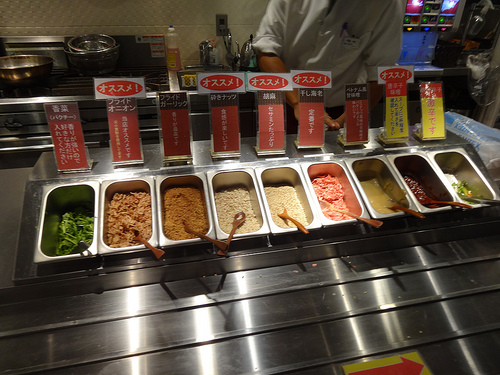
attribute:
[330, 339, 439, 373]
arrow — red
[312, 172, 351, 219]
food — pink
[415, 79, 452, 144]
sign — red , yellow 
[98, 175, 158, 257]
container — silver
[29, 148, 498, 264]
buffet — metal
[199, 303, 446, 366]
surface — reflective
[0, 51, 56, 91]
pan — reflective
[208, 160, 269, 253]
container — metal 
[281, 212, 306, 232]
stick — wooden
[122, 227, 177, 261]
stick — wooden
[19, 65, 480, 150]
signs — Chinese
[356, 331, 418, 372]
arrow — silver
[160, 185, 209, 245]
rice — brown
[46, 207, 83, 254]
vegetables — green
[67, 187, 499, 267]
spoons — wooden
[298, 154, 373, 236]
container — metal 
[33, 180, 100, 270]
container — silver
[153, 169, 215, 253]
container — silver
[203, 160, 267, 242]
container — silver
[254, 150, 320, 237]
container — silver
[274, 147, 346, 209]
container — metal 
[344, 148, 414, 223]
container — metal 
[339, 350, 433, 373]
sticker — yellow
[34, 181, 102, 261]
container — metal 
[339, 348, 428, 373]
arrow sign — yellow , red 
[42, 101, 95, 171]
sign — red 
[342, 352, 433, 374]
arrow — red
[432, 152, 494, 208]
container — silver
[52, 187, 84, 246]
food — green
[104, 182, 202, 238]
food — brown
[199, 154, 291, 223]
food — white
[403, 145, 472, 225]
food — red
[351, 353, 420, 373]
arrow — red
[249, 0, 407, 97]
shirt — light gray